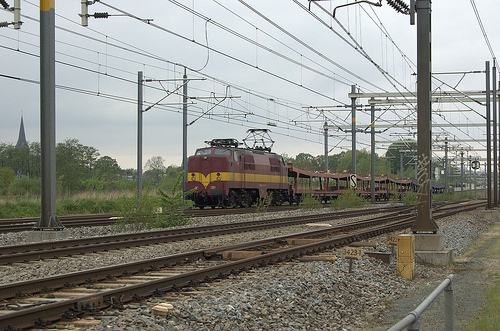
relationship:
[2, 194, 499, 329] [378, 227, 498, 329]
tracks on ground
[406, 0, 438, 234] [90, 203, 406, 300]
pole by track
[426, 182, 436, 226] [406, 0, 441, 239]
graffiti on pole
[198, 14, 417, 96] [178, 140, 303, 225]
wires above train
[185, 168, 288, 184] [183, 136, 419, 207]
stripe on train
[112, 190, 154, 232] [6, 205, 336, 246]
bush in gravel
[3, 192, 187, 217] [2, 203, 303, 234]
grass by tracks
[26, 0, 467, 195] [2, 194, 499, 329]
poles by tracks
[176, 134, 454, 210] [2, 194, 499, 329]
train on tracks